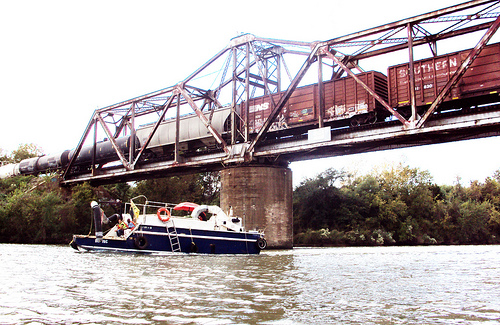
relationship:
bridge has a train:
[58, 0, 500, 248] [0, 41, 499, 192]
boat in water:
[69, 193, 267, 258] [1, 241, 500, 324]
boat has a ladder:
[69, 193, 267, 258] [165, 218, 181, 252]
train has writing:
[0, 41, 499, 192] [397, 57, 462, 78]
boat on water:
[69, 193, 267, 258] [1, 241, 500, 324]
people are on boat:
[115, 218, 138, 237] [69, 193, 267, 258]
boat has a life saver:
[69, 193, 267, 258] [156, 206, 172, 222]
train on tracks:
[0, 41, 499, 192] [59, 103, 500, 188]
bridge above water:
[58, 0, 500, 248] [1, 241, 500, 324]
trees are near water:
[0, 143, 500, 245] [1, 241, 500, 324]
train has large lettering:
[0, 41, 499, 192] [397, 57, 462, 78]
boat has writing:
[69, 193, 267, 258] [93, 236, 109, 244]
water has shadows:
[1, 241, 500, 324] [89, 248, 267, 258]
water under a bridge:
[1, 241, 500, 324] [58, 0, 500, 248]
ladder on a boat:
[165, 218, 181, 252] [69, 193, 267, 258]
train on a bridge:
[0, 41, 499, 192] [58, 0, 500, 248]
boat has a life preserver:
[69, 193, 267, 258] [156, 206, 172, 222]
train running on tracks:
[0, 41, 499, 192] [59, 103, 500, 188]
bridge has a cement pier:
[58, 0, 500, 248] [219, 167, 296, 252]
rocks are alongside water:
[0, 233, 500, 248] [1, 241, 500, 324]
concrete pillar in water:
[219, 167, 296, 252] [1, 241, 500, 324]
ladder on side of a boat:
[165, 218, 181, 252] [69, 193, 267, 258]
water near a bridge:
[1, 241, 500, 324] [58, 0, 500, 248]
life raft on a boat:
[156, 206, 172, 222] [69, 193, 267, 258]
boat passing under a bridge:
[69, 193, 267, 258] [58, 0, 500, 248]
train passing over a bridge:
[0, 41, 499, 192] [58, 0, 500, 248]